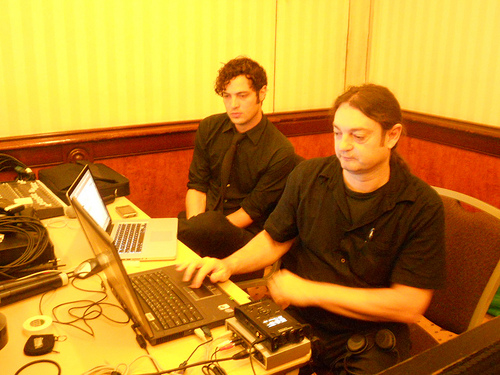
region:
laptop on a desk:
[72, 206, 230, 346]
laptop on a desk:
[75, 160, 180, 256]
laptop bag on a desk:
[50, 155, 125, 187]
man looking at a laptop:
[263, 76, 444, 306]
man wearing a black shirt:
[266, 78, 444, 324]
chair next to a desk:
[438, 175, 493, 340]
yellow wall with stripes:
[50, 73, 147, 121]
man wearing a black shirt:
[182, 33, 286, 208]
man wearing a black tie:
[187, 43, 276, 222]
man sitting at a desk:
[179, 40, 274, 222]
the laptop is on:
[49, 154, 196, 294]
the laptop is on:
[59, 132, 179, 250]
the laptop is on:
[75, 180, 140, 250]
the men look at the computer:
[180, 54, 441, 374]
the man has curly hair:
[216, 58, 268, 97]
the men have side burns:
[253, 92, 386, 145]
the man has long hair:
[335, 86, 411, 173]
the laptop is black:
[70, 200, 245, 334]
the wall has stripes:
[0, 3, 499, 140]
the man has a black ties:
[208, 129, 245, 218]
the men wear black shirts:
[188, 112, 446, 325]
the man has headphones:
[337, 333, 399, 369]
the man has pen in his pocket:
[364, 226, 375, 244]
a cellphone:
[115, 198, 149, 229]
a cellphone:
[112, 197, 166, 245]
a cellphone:
[110, 185, 141, 229]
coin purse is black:
[27, 328, 42, 353]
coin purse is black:
[37, 332, 49, 359]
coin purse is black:
[34, 345, 56, 357]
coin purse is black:
[33, 342, 50, 350]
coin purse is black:
[27, 340, 43, 350]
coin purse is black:
[38, 337, 47, 354]